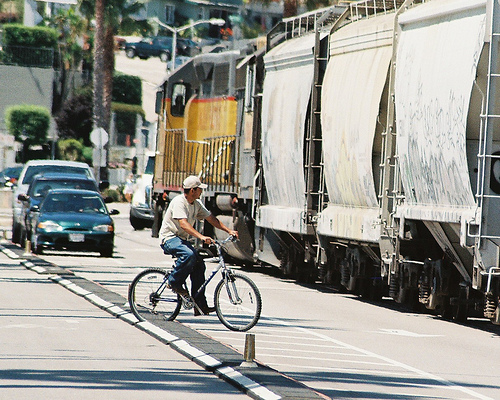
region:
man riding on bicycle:
[126, 166, 273, 343]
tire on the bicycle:
[206, 268, 276, 336]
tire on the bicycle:
[116, 268, 186, 337]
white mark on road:
[323, 366, 394, 383]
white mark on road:
[281, 349, 330, 362]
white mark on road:
[348, 375, 409, 390]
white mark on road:
[317, 364, 373, 374]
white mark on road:
[270, 346, 327, 353]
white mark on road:
[250, 333, 302, 340]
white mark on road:
[201, 329, 246, 334]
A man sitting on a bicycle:
[126, 172, 262, 330]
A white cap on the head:
[180, 171, 209, 193]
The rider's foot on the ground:
[195, 298, 217, 316]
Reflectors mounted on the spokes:
[248, 287, 253, 307]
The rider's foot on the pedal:
[166, 281, 190, 298]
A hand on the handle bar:
[223, 232, 239, 242]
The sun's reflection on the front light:
[42, 218, 62, 233]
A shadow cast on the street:
[51, 362, 208, 394]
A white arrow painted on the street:
[379, 321, 444, 342]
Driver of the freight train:
[171, 90, 188, 115]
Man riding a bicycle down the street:
[105, 161, 280, 334]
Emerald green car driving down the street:
[20, 180, 125, 260]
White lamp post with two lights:
[135, 0, 220, 70]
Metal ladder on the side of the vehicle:
[285, 16, 330, 276]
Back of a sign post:
[80, 120, 120, 175]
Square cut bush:
[5, 105, 50, 145]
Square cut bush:
[0, 20, 55, 66]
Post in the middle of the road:
[230, 326, 265, 381]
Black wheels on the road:
[271, 225, 476, 315]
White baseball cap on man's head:
[177, 172, 216, 193]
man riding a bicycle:
[121, 174, 263, 334]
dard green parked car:
[26, 186, 120, 258]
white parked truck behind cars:
[11, 156, 106, 243]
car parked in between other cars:
[17, 171, 110, 255]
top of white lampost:
[145, 10, 226, 80]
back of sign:
[86, 123, 110, 192]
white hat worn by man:
[181, 173, 208, 190]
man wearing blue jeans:
[127, 173, 265, 331]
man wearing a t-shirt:
[126, 170, 264, 330]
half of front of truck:
[126, 148, 161, 230]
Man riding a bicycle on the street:
[125, 170, 262, 337]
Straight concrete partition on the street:
[35, 257, 317, 399]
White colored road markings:
[102, 259, 494, 399]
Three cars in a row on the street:
[2, 152, 117, 257]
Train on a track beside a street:
[150, 130, 495, 340]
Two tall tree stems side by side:
[85, 5, 120, 205]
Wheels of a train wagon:
[280, 240, 495, 325]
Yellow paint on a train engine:
[151, 97, 231, 189]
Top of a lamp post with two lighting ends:
[141, 9, 228, 79]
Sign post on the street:
[88, 124, 109, 193]